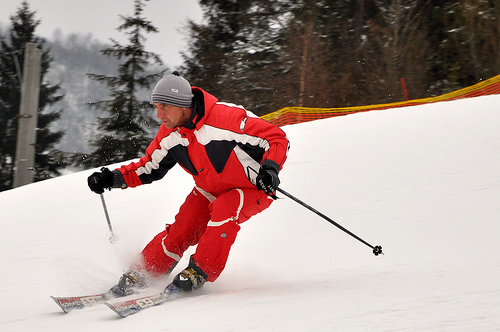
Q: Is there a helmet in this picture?
A: No, there are no helmets.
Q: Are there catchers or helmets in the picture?
A: No, there are no helmets or catchers.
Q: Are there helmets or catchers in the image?
A: No, there are no helmets or catchers.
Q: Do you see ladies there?
A: No, there are no ladies.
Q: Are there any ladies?
A: No, there are no ladies.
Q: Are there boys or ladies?
A: No, there are no ladies or boys.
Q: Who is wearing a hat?
A: The man is wearing a hat.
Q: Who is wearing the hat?
A: The man is wearing a hat.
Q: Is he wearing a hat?
A: Yes, the man is wearing a hat.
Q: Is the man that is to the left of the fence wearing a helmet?
A: No, the man is wearing a hat.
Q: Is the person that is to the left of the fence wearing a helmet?
A: No, the man is wearing a hat.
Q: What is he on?
A: The man is on the ski.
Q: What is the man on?
A: The man is on the ski.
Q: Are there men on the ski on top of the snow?
A: Yes, there is a man on the ski.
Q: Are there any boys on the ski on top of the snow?
A: No, there is a man on the ski.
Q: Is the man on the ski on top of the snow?
A: Yes, the man is on the ski.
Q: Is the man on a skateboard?
A: No, the man is on the ski.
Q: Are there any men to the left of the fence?
A: Yes, there is a man to the left of the fence.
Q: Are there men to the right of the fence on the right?
A: No, the man is to the left of the fence.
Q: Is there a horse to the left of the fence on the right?
A: No, there is a man to the left of the fence.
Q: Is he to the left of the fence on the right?
A: Yes, the man is to the left of the fence.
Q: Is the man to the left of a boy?
A: No, the man is to the left of the fence.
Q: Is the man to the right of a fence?
A: No, the man is to the left of a fence.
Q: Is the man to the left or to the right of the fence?
A: The man is to the left of the fence.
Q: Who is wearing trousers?
A: The man is wearing trousers.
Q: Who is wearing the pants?
A: The man is wearing trousers.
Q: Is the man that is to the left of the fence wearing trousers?
A: Yes, the man is wearing trousers.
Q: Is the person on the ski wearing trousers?
A: Yes, the man is wearing trousers.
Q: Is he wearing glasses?
A: No, the man is wearing trousers.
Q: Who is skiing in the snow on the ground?
A: The man is skiing in the snow.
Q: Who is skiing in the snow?
A: The man is skiing in the snow.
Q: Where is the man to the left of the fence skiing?
A: The man is skiing in the snow.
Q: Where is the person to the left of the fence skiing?
A: The man is skiing in the snow.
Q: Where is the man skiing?
A: The man is skiing in the snow.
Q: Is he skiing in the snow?
A: Yes, the man is skiing in the snow.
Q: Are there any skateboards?
A: No, there are no skateboards.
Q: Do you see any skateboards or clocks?
A: No, there are no skateboards or clocks.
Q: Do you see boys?
A: No, there are no boys.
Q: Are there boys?
A: No, there are no boys.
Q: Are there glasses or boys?
A: No, there are no boys or glasses.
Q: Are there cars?
A: No, there are no cars.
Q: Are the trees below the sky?
A: Yes, the trees are below the sky.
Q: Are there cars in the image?
A: No, there are no cars.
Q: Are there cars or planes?
A: No, there are no cars or planes.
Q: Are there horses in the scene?
A: No, there are no horses.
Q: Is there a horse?
A: No, there are no horses.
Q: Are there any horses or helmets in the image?
A: No, there are no horses or helmets.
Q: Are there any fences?
A: Yes, there is a fence.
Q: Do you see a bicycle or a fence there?
A: Yes, there is a fence.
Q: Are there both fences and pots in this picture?
A: No, there is a fence but no pots.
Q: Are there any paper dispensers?
A: No, there are no paper dispensers.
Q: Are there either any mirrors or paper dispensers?
A: No, there are no paper dispensers or mirrors.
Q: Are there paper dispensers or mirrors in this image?
A: No, there are no paper dispensers or mirrors.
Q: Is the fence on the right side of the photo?
A: Yes, the fence is on the right of the image.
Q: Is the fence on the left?
A: No, the fence is on the right of the image.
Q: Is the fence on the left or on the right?
A: The fence is on the right of the image.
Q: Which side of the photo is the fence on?
A: The fence is on the right of the image.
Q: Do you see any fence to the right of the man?
A: Yes, there is a fence to the right of the man.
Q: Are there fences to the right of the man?
A: Yes, there is a fence to the right of the man.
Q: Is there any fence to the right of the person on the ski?
A: Yes, there is a fence to the right of the man.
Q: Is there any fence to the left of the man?
A: No, the fence is to the right of the man.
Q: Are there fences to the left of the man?
A: No, the fence is to the right of the man.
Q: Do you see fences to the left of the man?
A: No, the fence is to the right of the man.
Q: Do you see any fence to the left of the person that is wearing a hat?
A: No, the fence is to the right of the man.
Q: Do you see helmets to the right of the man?
A: No, there is a fence to the right of the man.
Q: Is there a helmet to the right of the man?
A: No, there is a fence to the right of the man.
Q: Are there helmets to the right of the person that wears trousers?
A: No, there is a fence to the right of the man.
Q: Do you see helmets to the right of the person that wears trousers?
A: No, there is a fence to the right of the man.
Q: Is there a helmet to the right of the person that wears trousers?
A: No, there is a fence to the right of the man.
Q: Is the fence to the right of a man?
A: Yes, the fence is to the right of a man.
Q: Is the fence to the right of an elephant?
A: No, the fence is to the right of a man.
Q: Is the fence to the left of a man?
A: No, the fence is to the right of a man.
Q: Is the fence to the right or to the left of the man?
A: The fence is to the right of the man.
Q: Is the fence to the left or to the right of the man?
A: The fence is to the right of the man.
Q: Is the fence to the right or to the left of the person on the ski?
A: The fence is to the right of the man.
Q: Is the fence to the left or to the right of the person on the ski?
A: The fence is to the right of the man.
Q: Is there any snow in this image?
A: Yes, there is snow.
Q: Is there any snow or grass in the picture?
A: Yes, there is snow.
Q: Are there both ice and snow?
A: No, there is snow but no ice.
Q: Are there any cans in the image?
A: No, there are no cans.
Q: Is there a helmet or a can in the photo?
A: No, there are no cans or helmets.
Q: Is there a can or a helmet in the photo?
A: No, there are no cans or helmets.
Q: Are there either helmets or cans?
A: No, there are no cans or helmets.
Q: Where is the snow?
A: The snow is on the ground.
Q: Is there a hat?
A: Yes, there is a hat.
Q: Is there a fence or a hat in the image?
A: Yes, there is a hat.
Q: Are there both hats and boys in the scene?
A: No, there is a hat but no boys.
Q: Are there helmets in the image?
A: No, there are no helmets.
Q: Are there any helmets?
A: No, there are no helmets.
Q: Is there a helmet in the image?
A: No, there are no helmets.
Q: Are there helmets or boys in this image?
A: No, there are no helmets or boys.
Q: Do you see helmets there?
A: No, there are no helmets.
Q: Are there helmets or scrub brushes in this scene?
A: No, there are no helmets or scrub brushes.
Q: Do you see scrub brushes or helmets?
A: No, there are no helmets or scrub brushes.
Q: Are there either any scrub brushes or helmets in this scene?
A: No, there are no helmets or scrub brushes.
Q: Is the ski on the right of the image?
A: No, the ski is on the left of the image.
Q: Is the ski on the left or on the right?
A: The ski is on the left of the image.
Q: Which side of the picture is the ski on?
A: The ski is on the left of the image.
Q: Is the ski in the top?
A: No, the ski is in the bottom of the image.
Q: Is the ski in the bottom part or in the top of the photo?
A: The ski is in the bottom of the image.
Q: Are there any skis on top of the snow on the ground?
A: Yes, there is a ski on top of the snow.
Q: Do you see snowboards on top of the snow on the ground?
A: No, there is a ski on top of the snow.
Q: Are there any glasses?
A: No, there are no glasses.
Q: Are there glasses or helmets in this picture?
A: No, there are no glasses or helmets.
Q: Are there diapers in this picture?
A: No, there are no diapers.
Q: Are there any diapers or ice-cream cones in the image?
A: No, there are no diapers or ice-cream cones.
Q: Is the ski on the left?
A: Yes, the ski is on the left of the image.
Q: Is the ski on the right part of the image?
A: No, the ski is on the left of the image.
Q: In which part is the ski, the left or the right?
A: The ski is on the left of the image.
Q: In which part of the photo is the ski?
A: The ski is on the left of the image.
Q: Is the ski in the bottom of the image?
A: Yes, the ski is in the bottom of the image.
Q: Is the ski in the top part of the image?
A: No, the ski is in the bottom of the image.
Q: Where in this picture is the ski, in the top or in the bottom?
A: The ski is in the bottom of the image.